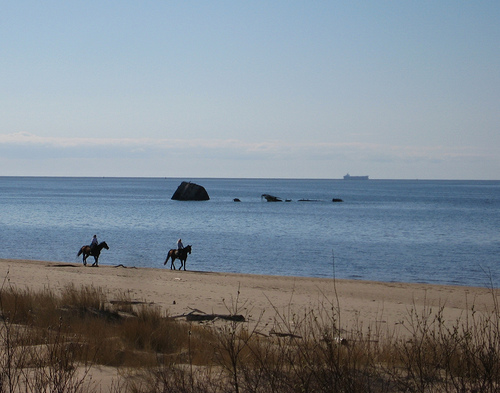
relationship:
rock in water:
[171, 181, 210, 201] [4, 173, 484, 287]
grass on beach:
[11, 290, 480, 390] [5, 257, 497, 391]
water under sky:
[4, 173, 484, 287] [2, 0, 498, 176]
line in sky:
[2, 131, 498, 143] [2, 0, 498, 176]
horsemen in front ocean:
[78, 237, 194, 271] [0, 179, 498, 282]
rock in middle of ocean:
[171, 181, 210, 201] [0, 179, 498, 282]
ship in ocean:
[343, 172, 369, 180] [0, 179, 498, 282]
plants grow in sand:
[216, 328, 497, 386] [249, 282, 498, 332]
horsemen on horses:
[89, 235, 98, 256] [76, 240, 106, 265]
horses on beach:
[74, 242, 112, 267] [11, 266, 498, 387]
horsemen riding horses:
[89, 235, 98, 256] [74, 242, 112, 267]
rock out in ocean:
[169, 179, 207, 200] [0, 179, 498, 282]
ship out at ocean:
[343, 172, 369, 180] [0, 179, 498, 282]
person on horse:
[174, 239, 186, 262] [162, 242, 192, 274]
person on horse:
[177, 239, 184, 259] [165, 242, 192, 267]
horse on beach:
[165, 242, 192, 267] [5, 257, 497, 391]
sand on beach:
[261, 291, 393, 292] [250, 280, 389, 315]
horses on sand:
[77, 241, 109, 267] [194, 272, 420, 319]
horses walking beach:
[77, 241, 109, 267] [2, 259, 482, 349]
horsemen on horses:
[89, 235, 98, 256] [75, 241, 196, 273]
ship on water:
[335, 172, 375, 186] [9, 180, 483, 279]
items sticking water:
[172, 177, 350, 211] [4, 173, 484, 287]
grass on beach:
[11, 290, 480, 390] [2, 259, 482, 349]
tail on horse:
[158, 249, 171, 269] [161, 236, 204, 276]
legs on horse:
[169, 259, 196, 269] [159, 237, 195, 275]